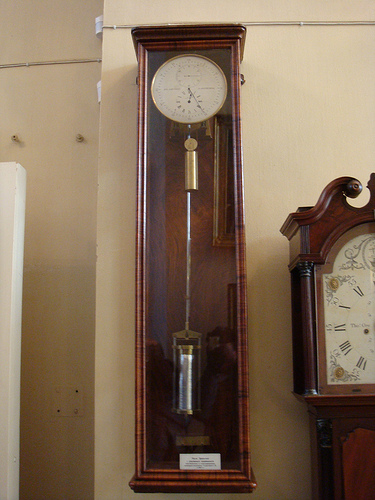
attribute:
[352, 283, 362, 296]
roman numerals — black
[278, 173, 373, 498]
clock — brown, wood, dark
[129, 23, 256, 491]
pendulum clock — unusual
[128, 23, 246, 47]
trim — wooden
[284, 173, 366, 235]
trim — wooden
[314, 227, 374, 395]
clock — white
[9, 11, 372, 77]
pipe — silver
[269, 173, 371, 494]
clock — dark, brown, wood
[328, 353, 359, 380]
design — Decorative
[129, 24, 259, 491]
brown clock — wood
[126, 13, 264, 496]
clock — white, floor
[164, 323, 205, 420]
pendulum — swinging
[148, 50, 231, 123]
clock — white, analog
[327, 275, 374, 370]
numerals — roman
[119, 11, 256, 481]
clock — brown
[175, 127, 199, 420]
chime — hanging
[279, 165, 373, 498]
case — carved 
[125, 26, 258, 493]
frame — wood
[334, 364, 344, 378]
mark — gold